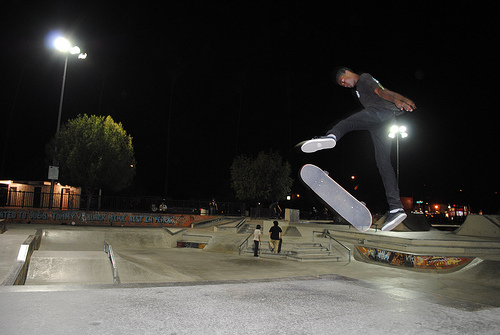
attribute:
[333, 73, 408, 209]
skateboarder — air, trick, skateboarding, airborne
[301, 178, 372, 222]
skateboard — air, white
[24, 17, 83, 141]
street light — shining, on, illuminated, background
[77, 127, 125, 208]
tree — leaf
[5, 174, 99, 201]
buildings — distant, lit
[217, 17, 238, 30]
sky — black, dark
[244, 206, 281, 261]
people — walking, standing, talking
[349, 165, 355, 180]
traffic signals — background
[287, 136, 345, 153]
shoe — black, bottom, side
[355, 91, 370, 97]
shirt — black, white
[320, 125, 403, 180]
pants — black